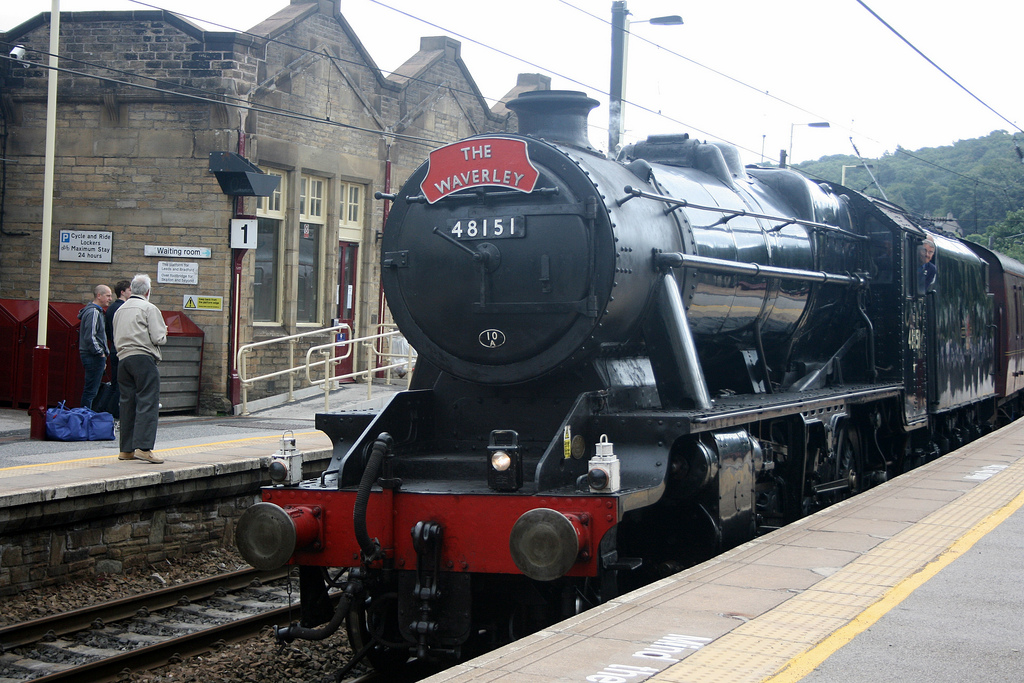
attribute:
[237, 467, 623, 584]
train bumper — red, silver